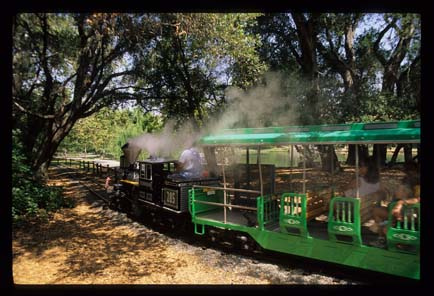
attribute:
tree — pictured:
[316, 15, 426, 161]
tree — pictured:
[248, 38, 422, 131]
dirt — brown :
[77, 210, 143, 284]